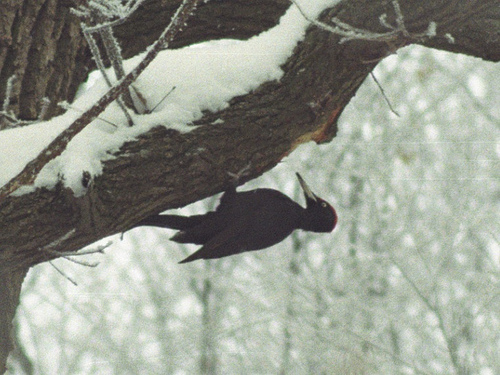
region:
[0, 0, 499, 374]
a wooded environment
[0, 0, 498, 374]
a large tree in the foreground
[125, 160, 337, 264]
a bird on the tree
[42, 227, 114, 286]
a small group of branches on the tree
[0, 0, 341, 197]
a pile of snow on the tree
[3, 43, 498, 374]
a group of snowy trees in the background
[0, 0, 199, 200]
a branch on the tree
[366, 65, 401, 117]
a small branch on the tree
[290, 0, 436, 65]
a small group of branches on the tree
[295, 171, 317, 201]
the bird's beak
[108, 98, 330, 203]
bark on tree branch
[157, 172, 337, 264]
bird with pointed beak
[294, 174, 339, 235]
head with white eyes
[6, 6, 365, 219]
snow on tree branch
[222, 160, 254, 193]
claw on bird foot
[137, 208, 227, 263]
black tail feathers of bird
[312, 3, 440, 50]
frosted twigs on tree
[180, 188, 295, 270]
black body of bird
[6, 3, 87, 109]
crevasses in tree bark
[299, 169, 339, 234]
head with beak and eye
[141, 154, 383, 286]
a bird on a branch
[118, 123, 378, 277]
a woodpecker on a tree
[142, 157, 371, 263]
a black and red woodpecker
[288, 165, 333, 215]
long beak of a woodpecker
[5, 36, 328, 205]
snow on a branch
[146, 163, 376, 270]
a black and red bird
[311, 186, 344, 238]
a red patch on it's head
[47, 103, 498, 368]
many tree branches without leaves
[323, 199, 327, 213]
an eye of the bird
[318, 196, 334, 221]
yellow eye of black bird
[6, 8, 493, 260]
The branch is brown.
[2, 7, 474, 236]
The branch is snow covered.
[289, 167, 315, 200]
The beak is tan.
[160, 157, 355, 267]
The bird is black.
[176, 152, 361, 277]
The bird is upside down.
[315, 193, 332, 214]
The eye is yellow.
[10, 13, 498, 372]
The trees are snow covered.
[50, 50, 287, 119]
The snow is white.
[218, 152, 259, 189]
His claws are in the bark.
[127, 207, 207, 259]
His tail is long.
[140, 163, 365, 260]
this is a bird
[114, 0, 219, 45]
the bark of a tree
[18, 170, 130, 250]
the bark of a tree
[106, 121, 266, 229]
the bark of a tree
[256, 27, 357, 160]
the bark of a tree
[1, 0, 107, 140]
the bark of a tree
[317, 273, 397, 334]
this is snow on the ground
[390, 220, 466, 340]
this is snow on the ground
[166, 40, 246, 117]
this is snow on the ground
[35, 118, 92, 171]
this is snow on the ground